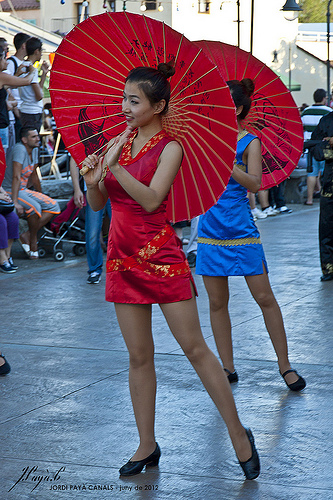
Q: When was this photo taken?
A: Daytime.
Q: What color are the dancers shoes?
A: Black.